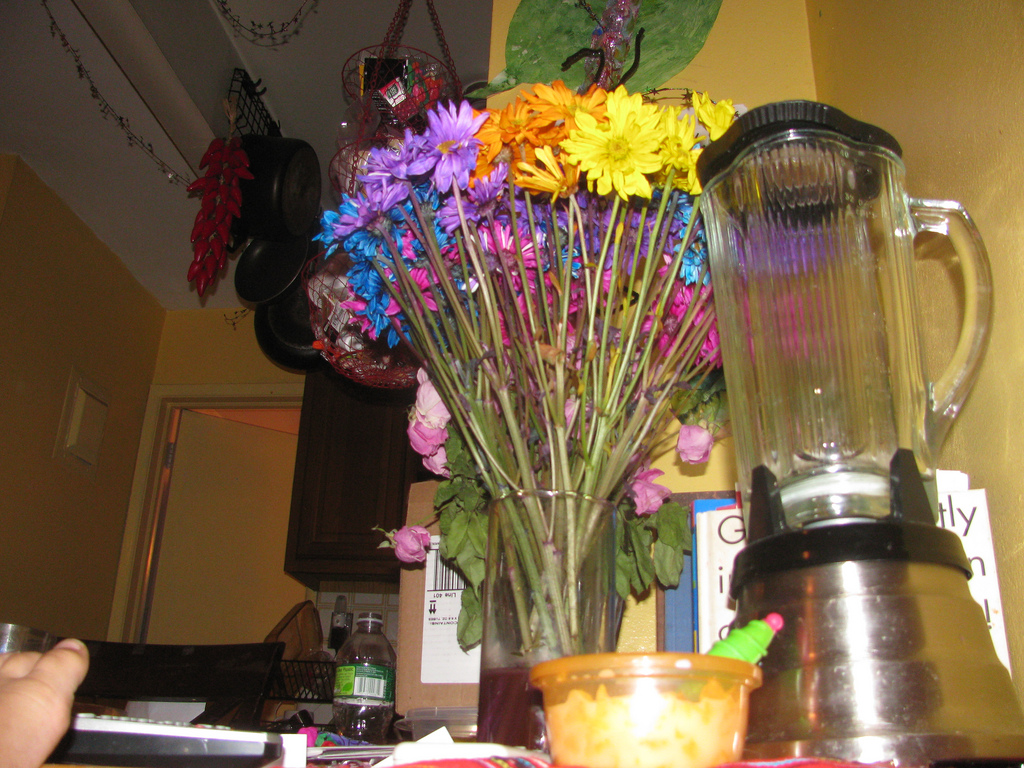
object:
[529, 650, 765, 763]
bowl